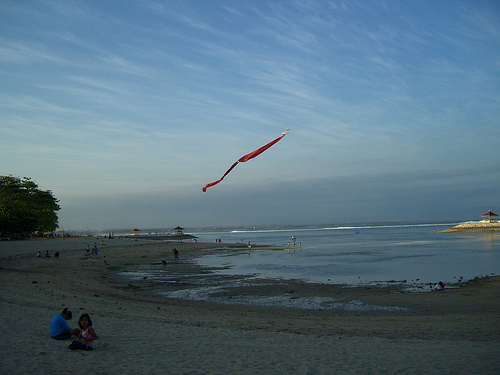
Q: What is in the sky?
A: Clouds.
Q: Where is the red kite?
A: In the air.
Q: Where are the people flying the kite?
A: At the beach.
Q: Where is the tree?
A: To the left.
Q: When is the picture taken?
A: Daytime.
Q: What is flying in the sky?
A: Kite.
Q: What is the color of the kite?
A: Red.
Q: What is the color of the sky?
A: Blue.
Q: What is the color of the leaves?
A: Green.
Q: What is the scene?
A: Beach.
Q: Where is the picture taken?
A: On a beach.